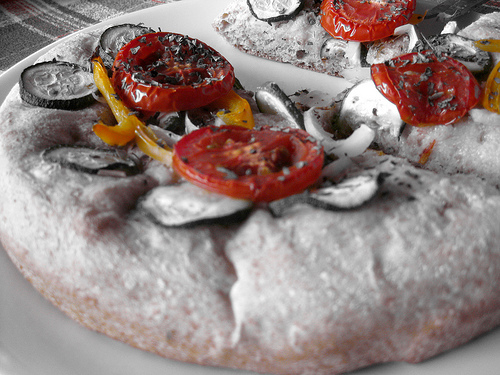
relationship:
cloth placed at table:
[8, 12, 58, 41] [417, 3, 432, 17]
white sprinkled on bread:
[267, 235, 345, 269] [18, 69, 498, 334]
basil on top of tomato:
[125, 32, 225, 92] [171, 124, 327, 199]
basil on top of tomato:
[125, 32, 225, 92] [371, 55, 477, 126]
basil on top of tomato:
[125, 32, 225, 92] [316, 0, 416, 39]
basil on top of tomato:
[125, 32, 225, 92] [113, 30, 234, 108]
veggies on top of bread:
[38, 16, 498, 200] [1, 24, 498, 374]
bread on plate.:
[451, 213, 483, 242] [88, 339, 141, 372]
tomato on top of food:
[174, 112, 319, 204] [14, 10, 498, 338]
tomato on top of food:
[365, 45, 476, 127] [25, 0, 498, 226]